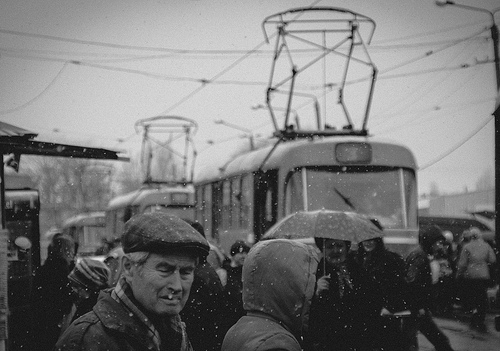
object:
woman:
[299, 237, 385, 351]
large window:
[219, 180, 233, 231]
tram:
[193, 5, 418, 262]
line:
[0, 2, 485, 135]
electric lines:
[133, 114, 199, 184]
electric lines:
[258, 5, 376, 138]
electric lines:
[73, 156, 117, 214]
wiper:
[332, 186, 384, 231]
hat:
[120, 212, 210, 256]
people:
[455, 229, 496, 333]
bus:
[194, 132, 424, 264]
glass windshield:
[283, 166, 418, 230]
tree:
[98, 162, 122, 219]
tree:
[70, 155, 96, 214]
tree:
[56, 160, 79, 217]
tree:
[42, 157, 62, 212]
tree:
[112, 149, 142, 194]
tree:
[24, 155, 43, 208]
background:
[0, 1, 499, 350]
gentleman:
[50, 211, 210, 351]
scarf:
[118, 280, 182, 351]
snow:
[52, 155, 234, 222]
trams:
[98, 113, 202, 246]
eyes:
[153, 265, 174, 277]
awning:
[0, 133, 129, 162]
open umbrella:
[259, 206, 385, 243]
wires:
[0, 27, 493, 55]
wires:
[0, 49, 500, 90]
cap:
[128, 205, 213, 250]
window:
[237, 171, 251, 229]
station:
[0, 54, 500, 350]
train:
[36, 127, 421, 297]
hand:
[313, 274, 332, 297]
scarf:
[325, 255, 357, 298]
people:
[221, 237, 326, 351]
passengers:
[0, 199, 500, 351]